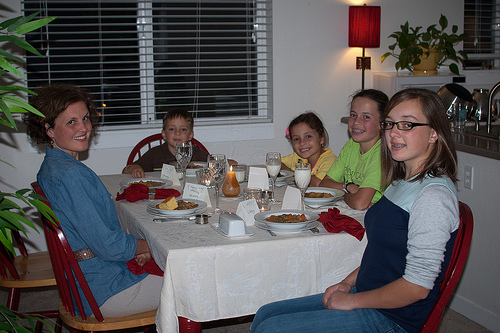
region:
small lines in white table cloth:
[179, 250, 241, 311]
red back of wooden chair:
[24, 217, 89, 310]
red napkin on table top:
[312, 204, 376, 239]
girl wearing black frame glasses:
[377, 114, 443, 138]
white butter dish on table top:
[212, 203, 253, 237]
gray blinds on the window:
[85, 16, 292, 99]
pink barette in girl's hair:
[274, 125, 298, 139]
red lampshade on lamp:
[338, 4, 393, 61]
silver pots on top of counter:
[440, 77, 494, 117]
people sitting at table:
[32, 82, 470, 302]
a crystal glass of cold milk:
[293, 161, 313, 208]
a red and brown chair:
[23, 178, 161, 331]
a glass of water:
[175, 140, 192, 182]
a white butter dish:
[211, 213, 255, 239]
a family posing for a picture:
[28, 82, 464, 332]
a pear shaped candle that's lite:
[219, 164, 241, 200]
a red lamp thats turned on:
[346, 0, 383, 88]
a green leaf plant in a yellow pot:
[381, 14, 473, 78]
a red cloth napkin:
[316, 205, 364, 242]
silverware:
[153, 212, 208, 224]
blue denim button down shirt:
[42, 149, 149, 311]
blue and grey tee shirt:
[362, 173, 457, 326]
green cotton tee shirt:
[328, 138, 383, 203]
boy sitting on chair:
[126, 108, 213, 172]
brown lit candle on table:
[223, 165, 240, 198]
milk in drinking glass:
[296, 161, 312, 191]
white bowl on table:
[267, 212, 309, 233]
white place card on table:
[237, 198, 259, 224]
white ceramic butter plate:
[220, 211, 245, 236]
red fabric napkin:
[317, 207, 364, 239]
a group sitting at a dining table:
[35, 80, 457, 276]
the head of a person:
[379, 87, 449, 164]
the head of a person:
[342, 85, 393, 143]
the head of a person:
[284, 110, 331, 161]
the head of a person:
[158, 107, 203, 148]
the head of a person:
[29, 80, 100, 156]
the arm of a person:
[329, 272, 439, 314]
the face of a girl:
[291, 120, 321, 155]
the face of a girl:
[346, 100, 378, 142]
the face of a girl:
[384, 107, 425, 159]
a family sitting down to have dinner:
[38, 82, 472, 324]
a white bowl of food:
[256, 205, 320, 230]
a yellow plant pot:
[412, 44, 443, 76]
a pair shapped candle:
[221, 165, 241, 194]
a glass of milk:
[294, 162, 311, 205]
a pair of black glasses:
[381, 119, 428, 131]